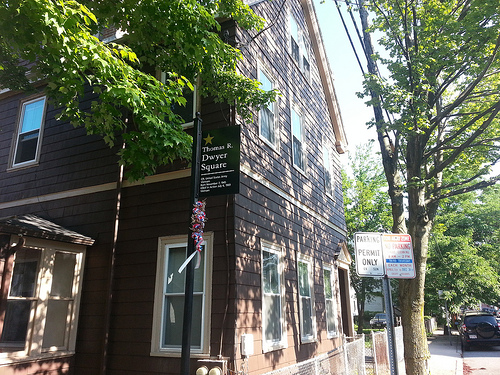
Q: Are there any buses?
A: No, there are no buses.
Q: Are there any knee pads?
A: No, there are no knee pads.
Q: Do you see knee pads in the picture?
A: No, there are no knee pads.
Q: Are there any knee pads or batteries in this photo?
A: No, there are no knee pads or batteries.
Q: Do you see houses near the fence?
A: Yes, there is a house near the fence.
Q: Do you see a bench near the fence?
A: No, there is a house near the fence.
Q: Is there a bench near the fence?
A: No, there is a house near the fence.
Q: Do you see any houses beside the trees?
A: Yes, there is a house beside the trees.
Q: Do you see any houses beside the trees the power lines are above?
A: Yes, there is a house beside the trees.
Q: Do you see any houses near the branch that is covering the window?
A: Yes, there is a house near the branch.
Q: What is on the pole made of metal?
A: The sign is on the pole.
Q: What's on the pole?
A: The sign is on the pole.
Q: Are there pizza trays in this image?
A: No, there are no pizza trays.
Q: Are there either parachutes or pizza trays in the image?
A: No, there are no pizza trays or parachutes.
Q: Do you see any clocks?
A: No, there are no clocks.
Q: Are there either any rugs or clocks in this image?
A: No, there are no clocks or rugs.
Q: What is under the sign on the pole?
A: The flowers are under the sign.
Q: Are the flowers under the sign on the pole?
A: Yes, the flowers are under the sign.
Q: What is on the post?
A: The sign is on the post.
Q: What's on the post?
A: The sign is on the post.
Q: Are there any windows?
A: Yes, there is a window.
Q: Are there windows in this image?
A: Yes, there is a window.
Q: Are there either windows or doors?
A: Yes, there is a window.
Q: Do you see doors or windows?
A: Yes, there is a window.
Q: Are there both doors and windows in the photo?
A: Yes, there are both a window and a door.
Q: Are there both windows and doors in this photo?
A: Yes, there are both a window and a door.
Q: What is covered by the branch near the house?
A: The window is covered by the branch.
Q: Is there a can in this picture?
A: No, there are no cans.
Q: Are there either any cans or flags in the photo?
A: No, there are no cans or flags.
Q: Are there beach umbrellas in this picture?
A: No, there are no beach umbrellas.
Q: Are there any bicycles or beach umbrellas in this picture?
A: No, there are no beach umbrellas or bicycles.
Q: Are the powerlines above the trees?
A: Yes, the powerlines are above the trees.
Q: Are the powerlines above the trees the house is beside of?
A: Yes, the powerlines are above the trees.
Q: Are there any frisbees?
A: No, there are no frisbees.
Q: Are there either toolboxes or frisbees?
A: No, there are no frisbees or toolboxes.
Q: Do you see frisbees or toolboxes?
A: No, there are no frisbees or toolboxes.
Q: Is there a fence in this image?
A: Yes, there is a fence.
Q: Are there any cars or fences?
A: Yes, there is a fence.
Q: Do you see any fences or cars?
A: Yes, there is a fence.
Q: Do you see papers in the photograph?
A: No, there are no papers.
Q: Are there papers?
A: No, there are no papers.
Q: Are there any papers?
A: No, there are no papers.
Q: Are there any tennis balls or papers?
A: No, there are no papers or tennis balls.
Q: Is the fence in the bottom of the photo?
A: Yes, the fence is in the bottom of the image.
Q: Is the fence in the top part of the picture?
A: No, the fence is in the bottom of the image.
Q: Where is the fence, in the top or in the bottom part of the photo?
A: The fence is in the bottom of the image.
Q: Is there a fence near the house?
A: Yes, there is a fence near the house.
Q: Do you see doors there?
A: Yes, there is a door.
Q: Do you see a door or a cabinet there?
A: Yes, there is a door.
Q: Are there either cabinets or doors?
A: Yes, there is a door.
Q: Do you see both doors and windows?
A: Yes, there are both a door and a window.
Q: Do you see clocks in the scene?
A: No, there are no clocks.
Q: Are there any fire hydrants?
A: No, there are no fire hydrants.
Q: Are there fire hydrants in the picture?
A: No, there are no fire hydrants.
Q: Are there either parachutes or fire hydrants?
A: No, there are no fire hydrants or parachutes.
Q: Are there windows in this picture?
A: Yes, there is a window.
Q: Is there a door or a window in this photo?
A: Yes, there is a window.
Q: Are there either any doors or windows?
A: Yes, there is a window.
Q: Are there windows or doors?
A: Yes, there is a window.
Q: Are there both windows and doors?
A: Yes, there are both a window and a door.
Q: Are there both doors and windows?
A: Yes, there are both a window and a door.